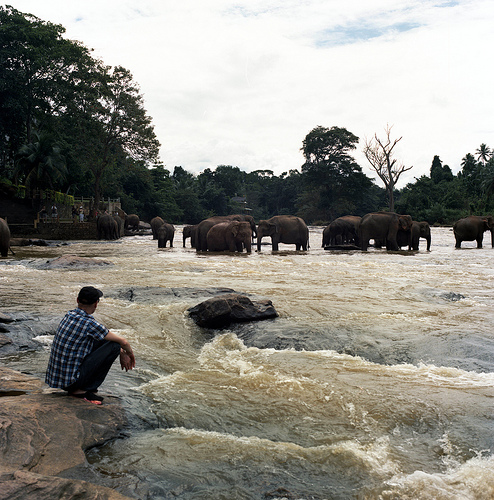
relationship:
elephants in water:
[88, 208, 493, 255] [3, 229, 493, 497]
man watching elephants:
[47, 286, 135, 405] [88, 208, 493, 255]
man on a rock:
[47, 286, 135, 405] [2, 372, 131, 499]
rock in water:
[184, 287, 278, 331] [3, 229, 493, 497]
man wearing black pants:
[47, 286, 135, 405] [77, 341, 122, 397]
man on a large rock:
[47, 286, 135, 405] [2, 372, 131, 499]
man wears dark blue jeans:
[47, 286, 135, 405] [77, 341, 122, 397]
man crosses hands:
[47, 286, 135, 405] [117, 347, 136, 374]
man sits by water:
[47, 286, 135, 405] [3, 229, 493, 497]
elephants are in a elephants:
[88, 208, 493, 255] [453, 216, 494, 248]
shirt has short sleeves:
[43, 307, 107, 387] [91, 318, 108, 346]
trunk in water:
[425, 235, 434, 253] [3, 229, 493, 497]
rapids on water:
[146, 290, 492, 499] [3, 229, 493, 497]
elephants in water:
[453, 216, 494, 248] [3, 229, 493, 497]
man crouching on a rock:
[47, 286, 135, 405] [2, 372, 131, 499]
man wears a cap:
[47, 286, 135, 405] [77, 283, 104, 304]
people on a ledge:
[28, 199, 86, 229] [13, 222, 128, 240]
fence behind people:
[4, 180, 128, 219] [28, 199, 86, 229]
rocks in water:
[1, 232, 66, 389] [3, 229, 493, 497]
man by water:
[47, 286, 135, 405] [3, 229, 493, 497]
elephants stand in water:
[88, 208, 493, 255] [3, 229, 493, 497]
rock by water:
[2, 372, 131, 499] [3, 229, 493, 497]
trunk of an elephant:
[254, 232, 265, 253] [255, 215, 311, 256]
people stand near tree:
[28, 199, 86, 229] [19, 129, 77, 221]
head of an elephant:
[229, 215, 256, 256] [208, 218, 255, 259]